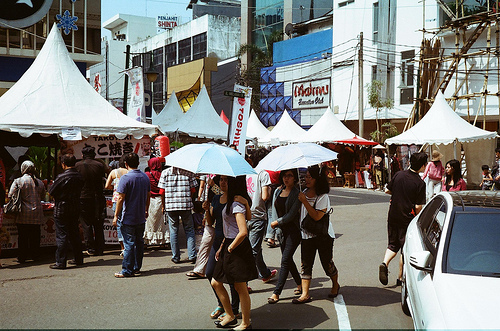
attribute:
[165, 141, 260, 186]
umbrella — blue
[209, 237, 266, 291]
skirt — black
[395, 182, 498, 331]
car — white, parked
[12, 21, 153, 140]
tent — white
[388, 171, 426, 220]
tshirt — black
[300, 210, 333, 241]
bag — black